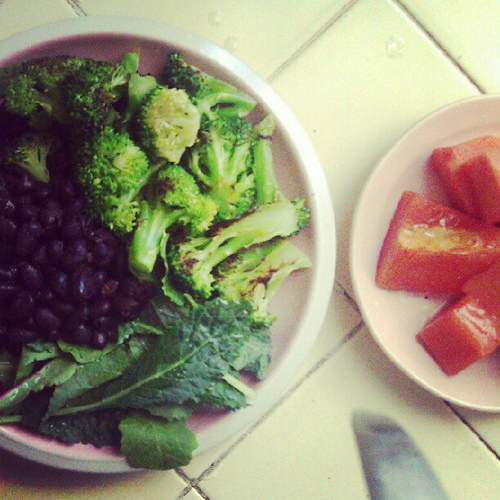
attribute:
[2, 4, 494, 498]
counter top — white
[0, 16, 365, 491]
bowl — white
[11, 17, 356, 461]
plates — white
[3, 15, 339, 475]
bowl — white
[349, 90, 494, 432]
plate — white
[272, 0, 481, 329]
tile — white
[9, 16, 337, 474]
plate — white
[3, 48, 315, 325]
broccoli — green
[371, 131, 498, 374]
tomatoes — cut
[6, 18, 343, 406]
bowl — white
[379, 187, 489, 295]
tomato — cut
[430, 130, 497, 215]
tomato — cut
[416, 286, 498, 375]
tomato — cut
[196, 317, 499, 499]
tile — white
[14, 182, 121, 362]
beans — black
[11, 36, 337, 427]
plate — white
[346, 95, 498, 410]
plate — white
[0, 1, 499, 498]
tiles — white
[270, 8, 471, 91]
tile — white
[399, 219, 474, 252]
blob — yellow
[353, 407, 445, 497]
object — silver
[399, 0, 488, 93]
grout — dark